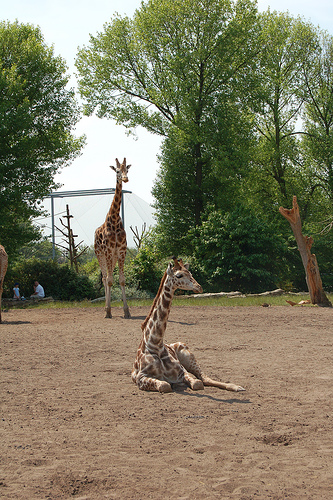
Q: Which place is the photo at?
A: It is at the field.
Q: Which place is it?
A: It is a field.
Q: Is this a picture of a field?
A: Yes, it is showing a field.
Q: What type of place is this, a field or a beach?
A: It is a field.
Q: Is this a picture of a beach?
A: No, the picture is showing a field.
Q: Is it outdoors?
A: Yes, it is outdoors.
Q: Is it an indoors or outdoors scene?
A: It is outdoors.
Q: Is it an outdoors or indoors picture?
A: It is outdoors.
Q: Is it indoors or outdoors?
A: It is outdoors.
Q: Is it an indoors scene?
A: No, it is outdoors.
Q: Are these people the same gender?
A: No, they are both male and female.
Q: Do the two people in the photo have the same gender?
A: No, they are both male and female.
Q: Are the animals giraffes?
A: Yes, all the animals are giraffes.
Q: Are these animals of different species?
A: No, all the animals are giraffes.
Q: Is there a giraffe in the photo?
A: Yes, there is a giraffe.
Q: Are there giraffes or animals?
A: Yes, there is a giraffe.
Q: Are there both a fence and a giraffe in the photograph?
A: No, there is a giraffe but no fences.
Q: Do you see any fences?
A: No, there are no fences.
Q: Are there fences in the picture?
A: No, there are no fences.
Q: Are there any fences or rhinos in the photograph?
A: No, there are no fences or rhinos.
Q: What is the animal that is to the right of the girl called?
A: The animal is a giraffe.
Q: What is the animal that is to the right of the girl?
A: The animal is a giraffe.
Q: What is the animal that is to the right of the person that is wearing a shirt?
A: The animal is a giraffe.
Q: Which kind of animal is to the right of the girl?
A: The animal is a giraffe.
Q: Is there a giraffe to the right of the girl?
A: Yes, there is a giraffe to the right of the girl.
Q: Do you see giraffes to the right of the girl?
A: Yes, there is a giraffe to the right of the girl.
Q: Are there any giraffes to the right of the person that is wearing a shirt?
A: Yes, there is a giraffe to the right of the girl.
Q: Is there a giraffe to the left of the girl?
A: No, the giraffe is to the right of the girl.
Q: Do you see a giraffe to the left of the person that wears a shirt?
A: No, the giraffe is to the right of the girl.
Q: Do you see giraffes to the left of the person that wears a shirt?
A: No, the giraffe is to the right of the girl.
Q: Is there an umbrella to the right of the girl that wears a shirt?
A: No, there is a giraffe to the right of the girl.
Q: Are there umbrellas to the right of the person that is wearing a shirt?
A: No, there is a giraffe to the right of the girl.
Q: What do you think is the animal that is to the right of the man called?
A: The animal is a giraffe.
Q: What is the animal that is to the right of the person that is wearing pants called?
A: The animal is a giraffe.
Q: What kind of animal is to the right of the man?
A: The animal is a giraffe.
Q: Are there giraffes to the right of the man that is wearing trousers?
A: Yes, there is a giraffe to the right of the man.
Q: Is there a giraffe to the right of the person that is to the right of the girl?
A: Yes, there is a giraffe to the right of the man.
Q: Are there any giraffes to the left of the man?
A: No, the giraffe is to the right of the man.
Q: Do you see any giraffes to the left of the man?
A: No, the giraffe is to the right of the man.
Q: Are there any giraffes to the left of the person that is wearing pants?
A: No, the giraffe is to the right of the man.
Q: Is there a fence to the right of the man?
A: No, there is a giraffe to the right of the man.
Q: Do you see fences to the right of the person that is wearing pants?
A: No, there is a giraffe to the right of the man.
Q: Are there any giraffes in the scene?
A: Yes, there is a giraffe.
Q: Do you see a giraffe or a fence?
A: Yes, there is a giraffe.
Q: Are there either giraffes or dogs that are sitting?
A: Yes, the giraffe is sitting.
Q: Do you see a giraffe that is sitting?
A: Yes, there is a giraffe that is sitting.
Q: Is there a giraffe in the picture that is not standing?
A: Yes, there is a giraffe that is sitting.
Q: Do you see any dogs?
A: No, there are no dogs.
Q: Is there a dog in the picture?
A: No, there are no dogs.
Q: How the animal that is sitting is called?
A: The animal is a giraffe.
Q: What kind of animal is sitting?
A: The animal is a giraffe.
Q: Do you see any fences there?
A: No, there are no fences.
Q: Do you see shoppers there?
A: No, there are no shoppers.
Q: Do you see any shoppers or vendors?
A: No, there are no shoppers or vendors.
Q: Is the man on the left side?
A: Yes, the man is on the left of the image.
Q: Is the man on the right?
A: No, the man is on the left of the image.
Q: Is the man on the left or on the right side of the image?
A: The man is on the left of the image.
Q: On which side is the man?
A: The man is on the left of the image.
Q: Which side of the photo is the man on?
A: The man is on the left of the image.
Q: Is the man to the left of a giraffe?
A: Yes, the man is to the left of a giraffe.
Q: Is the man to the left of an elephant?
A: No, the man is to the left of a giraffe.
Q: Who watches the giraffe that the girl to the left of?
A: The man watches the giraffe.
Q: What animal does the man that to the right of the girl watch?
A: The man watches the giraffe.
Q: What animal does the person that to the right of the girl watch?
A: The man watches the giraffe.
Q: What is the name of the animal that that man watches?
A: The animal is a giraffe.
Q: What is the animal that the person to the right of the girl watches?
A: The animal is a giraffe.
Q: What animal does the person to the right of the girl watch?
A: The man watches the giraffe.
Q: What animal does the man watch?
A: The man watches the giraffe.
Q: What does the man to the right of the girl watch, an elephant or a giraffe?
A: The man watches a giraffe.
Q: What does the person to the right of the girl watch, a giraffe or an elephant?
A: The man watches a giraffe.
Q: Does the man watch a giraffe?
A: Yes, the man watches a giraffe.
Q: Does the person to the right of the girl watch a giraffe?
A: Yes, the man watches a giraffe.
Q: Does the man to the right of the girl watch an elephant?
A: No, the man watches a giraffe.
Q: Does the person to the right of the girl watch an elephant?
A: No, the man watches a giraffe.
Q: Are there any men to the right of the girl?
A: Yes, there is a man to the right of the girl.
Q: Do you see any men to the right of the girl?
A: Yes, there is a man to the right of the girl.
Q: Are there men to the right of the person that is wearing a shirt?
A: Yes, there is a man to the right of the girl.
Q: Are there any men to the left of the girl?
A: No, the man is to the right of the girl.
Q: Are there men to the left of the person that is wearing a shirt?
A: No, the man is to the right of the girl.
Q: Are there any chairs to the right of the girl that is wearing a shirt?
A: No, there is a man to the right of the girl.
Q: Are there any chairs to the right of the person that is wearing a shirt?
A: No, there is a man to the right of the girl.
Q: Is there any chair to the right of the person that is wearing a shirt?
A: No, there is a man to the right of the girl.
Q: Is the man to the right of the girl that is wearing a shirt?
A: Yes, the man is to the right of the girl.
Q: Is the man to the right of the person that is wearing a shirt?
A: Yes, the man is to the right of the girl.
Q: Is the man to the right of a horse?
A: No, the man is to the right of the girl.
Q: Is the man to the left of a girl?
A: No, the man is to the right of a girl.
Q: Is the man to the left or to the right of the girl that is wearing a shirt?
A: The man is to the right of the girl.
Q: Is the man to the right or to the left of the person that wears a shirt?
A: The man is to the right of the girl.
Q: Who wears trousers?
A: The man wears trousers.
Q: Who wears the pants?
A: The man wears trousers.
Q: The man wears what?
A: The man wears trousers.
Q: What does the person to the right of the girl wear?
A: The man wears trousers.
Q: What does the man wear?
A: The man wears trousers.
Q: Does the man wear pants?
A: Yes, the man wears pants.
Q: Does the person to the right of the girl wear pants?
A: Yes, the man wears pants.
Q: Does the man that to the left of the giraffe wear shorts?
A: No, the man wears pants.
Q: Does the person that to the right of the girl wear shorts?
A: No, the man wears pants.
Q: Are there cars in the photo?
A: No, there are no cars.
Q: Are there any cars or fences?
A: No, there are no cars or fences.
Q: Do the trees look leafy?
A: Yes, the trees are leafy.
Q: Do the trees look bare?
A: No, the trees are leafy.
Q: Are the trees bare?
A: No, the trees are leafy.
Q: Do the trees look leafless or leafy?
A: The trees are leafy.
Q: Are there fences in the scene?
A: No, there are no fences.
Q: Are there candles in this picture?
A: No, there are no candles.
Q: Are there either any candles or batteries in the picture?
A: No, there are no candles or batteries.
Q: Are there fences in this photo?
A: No, there are no fences.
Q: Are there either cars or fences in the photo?
A: No, there are no fences or cars.